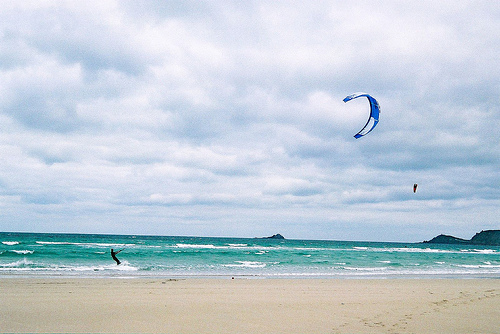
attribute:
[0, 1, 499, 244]
sky — cloudy, gray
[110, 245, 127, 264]
person — water gliding, parasailing, wearing black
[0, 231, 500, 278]
water — teal, blue, white, bright blue, green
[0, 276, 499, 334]
sand — brown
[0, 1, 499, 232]
clouds — white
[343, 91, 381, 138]
kite — blue, white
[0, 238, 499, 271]
wave — white, small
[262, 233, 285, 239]
island — blue